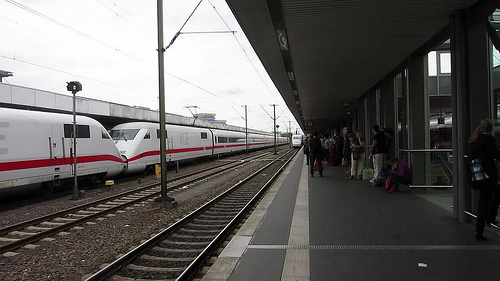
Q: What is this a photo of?
A: A train station.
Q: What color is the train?
A: Silver and red.